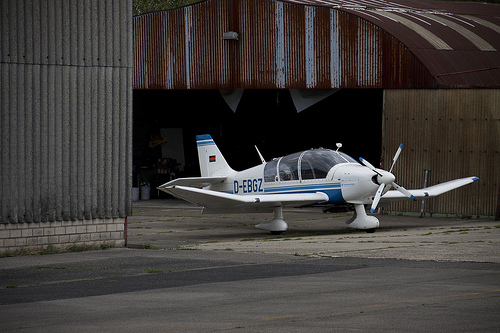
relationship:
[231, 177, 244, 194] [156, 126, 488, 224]
d on plane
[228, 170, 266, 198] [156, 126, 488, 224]
d-e8gz on plane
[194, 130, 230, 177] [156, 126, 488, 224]
tail of plane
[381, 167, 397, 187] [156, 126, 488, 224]
nose of plane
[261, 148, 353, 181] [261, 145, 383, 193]
windows on cockpit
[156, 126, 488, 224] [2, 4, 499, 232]
plane near hangar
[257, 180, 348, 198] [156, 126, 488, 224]
stripe on plane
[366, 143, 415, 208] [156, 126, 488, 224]
propeller on plane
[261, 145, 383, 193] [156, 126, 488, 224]
cockpit on plane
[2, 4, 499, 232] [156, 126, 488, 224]
hangar behind plane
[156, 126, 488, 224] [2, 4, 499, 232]
plane next to hangar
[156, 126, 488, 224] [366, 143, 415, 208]
plane has a propeller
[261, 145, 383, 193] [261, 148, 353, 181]
cockpit has windows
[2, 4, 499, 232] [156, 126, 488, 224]
hangar by plane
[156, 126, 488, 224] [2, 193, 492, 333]
plane on concrete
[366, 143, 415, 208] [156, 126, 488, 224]
propeller of plane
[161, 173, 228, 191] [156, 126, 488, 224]
vertical stabilizer of plane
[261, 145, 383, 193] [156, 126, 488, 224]
cockpit of plane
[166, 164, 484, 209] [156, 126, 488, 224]
wings of plane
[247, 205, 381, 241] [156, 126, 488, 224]
landing gear of plane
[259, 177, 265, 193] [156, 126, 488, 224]
z on th plane